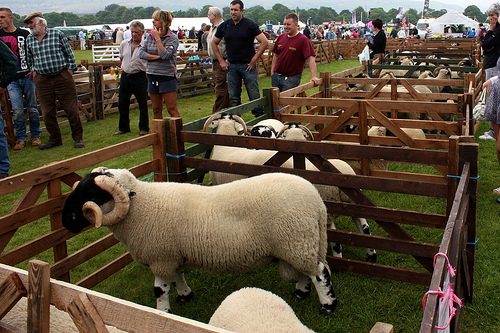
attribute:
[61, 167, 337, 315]
ram — male, black, white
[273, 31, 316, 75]
shirt — maroon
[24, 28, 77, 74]
shirt — plaid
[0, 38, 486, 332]
enclosures — wooden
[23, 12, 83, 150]
man — standing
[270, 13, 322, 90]
man — leaning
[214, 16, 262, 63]
shirt — black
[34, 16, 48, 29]
hair — gray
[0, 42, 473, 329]
sheep — together, separated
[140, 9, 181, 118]
woman — standing